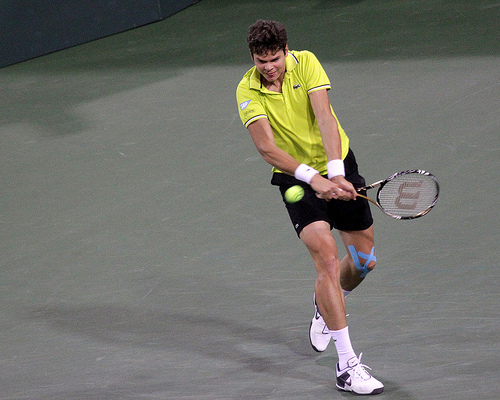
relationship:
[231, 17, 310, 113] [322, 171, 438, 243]
player holding racket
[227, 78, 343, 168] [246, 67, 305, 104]
shirt has collar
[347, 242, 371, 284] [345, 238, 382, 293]
stickers on knee